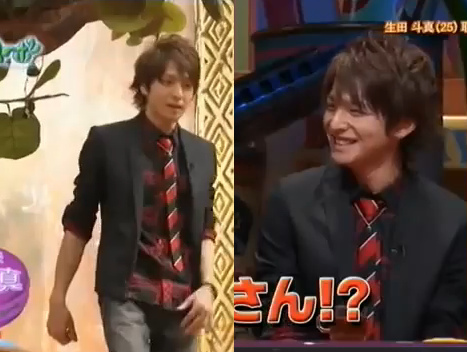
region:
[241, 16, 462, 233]
a young man smiling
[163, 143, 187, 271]
a strip tie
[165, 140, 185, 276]
a black red and white tie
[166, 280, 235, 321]
left hand of man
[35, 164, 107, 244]
selves of a coat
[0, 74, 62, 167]
a tree leaf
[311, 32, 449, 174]
a head of a young man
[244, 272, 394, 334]
writing on front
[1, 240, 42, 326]
symbols white and purple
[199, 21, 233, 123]
designs on a wall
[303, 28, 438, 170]
a young man with black hair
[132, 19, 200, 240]
a young man wearing a tie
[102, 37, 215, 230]
a young man wearing a suit jacket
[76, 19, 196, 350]
a young man wearing jeans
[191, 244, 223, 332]
a young man wearing a watch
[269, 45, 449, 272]
a young man wearing a necklace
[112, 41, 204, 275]
a young man wearing a red and black shirt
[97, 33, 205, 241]
a young man wearing a jacket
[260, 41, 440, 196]
a young man with his head turned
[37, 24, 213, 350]
a young man walking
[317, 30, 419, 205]
A man's smilling face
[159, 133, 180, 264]
A black stripped brown tie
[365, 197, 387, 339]
A black stripped brown tie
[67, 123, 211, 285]
Nevy blue fitting blezers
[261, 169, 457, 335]
Nevy blue fitting blezers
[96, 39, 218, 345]
A slim man walking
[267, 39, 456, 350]
A man sitting smilling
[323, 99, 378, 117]
Small slim chinise eyes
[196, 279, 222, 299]
A Black slim braclet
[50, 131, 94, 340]
An arm of a man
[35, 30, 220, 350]
this is a man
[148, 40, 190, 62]
the hair is long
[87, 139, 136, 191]
this is a suit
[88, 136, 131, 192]
the suit is black in color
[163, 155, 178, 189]
the tie is red in color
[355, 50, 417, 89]
the hair is long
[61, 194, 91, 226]
the suit is folded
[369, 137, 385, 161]
the boy is light skinned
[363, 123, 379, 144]
the boy is light skinned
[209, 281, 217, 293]
he is wearing a watch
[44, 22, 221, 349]
man wearing jacket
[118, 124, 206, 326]
man wearing red and black shirt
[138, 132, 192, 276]
the tie is red and black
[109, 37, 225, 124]
his hair is long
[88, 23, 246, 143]
his hair is disordered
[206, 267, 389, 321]
words on the screen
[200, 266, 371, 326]
the characters are orange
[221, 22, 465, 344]
the man is smiling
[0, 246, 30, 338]
the half-disk is purple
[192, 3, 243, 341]
the frame is yellow